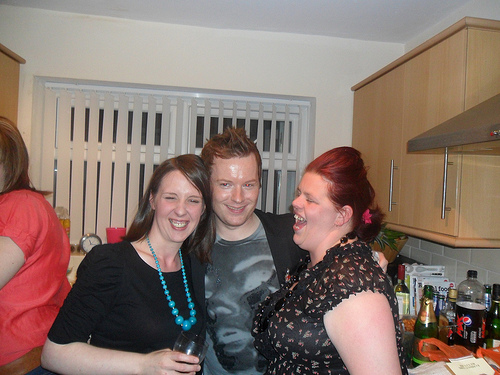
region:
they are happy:
[150, 152, 355, 255]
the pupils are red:
[205, 177, 257, 184]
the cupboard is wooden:
[377, 87, 437, 127]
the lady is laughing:
[288, 198, 310, 225]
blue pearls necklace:
[166, 274, 197, 334]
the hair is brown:
[308, 158, 387, 208]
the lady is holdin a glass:
[161, 322, 216, 374]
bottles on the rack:
[417, 272, 491, 342]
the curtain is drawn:
[77, 106, 142, 212]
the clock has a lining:
[72, 234, 97, 253]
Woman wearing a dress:
[46, 236, 209, 372]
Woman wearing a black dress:
[50, 236, 212, 358]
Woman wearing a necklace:
[136, 229, 200, 334]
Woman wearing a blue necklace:
[140, 227, 199, 332]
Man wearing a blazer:
[189, 210, 311, 320]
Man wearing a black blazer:
[187, 209, 309, 295]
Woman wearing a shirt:
[1, 185, 79, 364]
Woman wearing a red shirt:
[2, 186, 78, 364]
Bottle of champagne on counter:
[409, 280, 444, 367]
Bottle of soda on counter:
[453, 267, 489, 357]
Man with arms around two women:
[41, 124, 404, 374]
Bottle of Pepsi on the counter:
[454, 265, 484, 355]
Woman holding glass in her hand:
[37, 152, 209, 373]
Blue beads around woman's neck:
[143, 236, 198, 330]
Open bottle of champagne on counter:
[409, 280, 437, 360]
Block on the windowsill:
[79, 230, 100, 261]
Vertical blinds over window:
[35, 79, 317, 246]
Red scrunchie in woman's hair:
[360, 204, 375, 232]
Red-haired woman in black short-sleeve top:
[252, 144, 404, 373]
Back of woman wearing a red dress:
[0, 111, 73, 368]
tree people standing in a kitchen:
[71, 111, 418, 373]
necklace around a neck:
[140, 230, 202, 330]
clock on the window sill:
[80, 229, 103, 259]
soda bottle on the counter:
[454, 267, 487, 349]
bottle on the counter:
[415, 280, 442, 342]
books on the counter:
[400, 253, 446, 294]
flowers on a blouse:
[335, 260, 377, 285]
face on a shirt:
[205, 253, 261, 352]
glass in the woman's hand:
[170, 325, 213, 367]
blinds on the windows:
[52, 92, 123, 187]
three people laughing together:
[102, 105, 402, 322]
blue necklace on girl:
[160, 240, 205, 336]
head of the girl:
[131, 151, 211, 251]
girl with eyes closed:
[267, 140, 392, 259]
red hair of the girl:
[321, 138, 396, 239]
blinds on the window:
[36, 99, 150, 196]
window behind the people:
[54, 82, 172, 166]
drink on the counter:
[446, 262, 493, 354]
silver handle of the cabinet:
[379, 148, 409, 215]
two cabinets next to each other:
[376, 145, 467, 214]